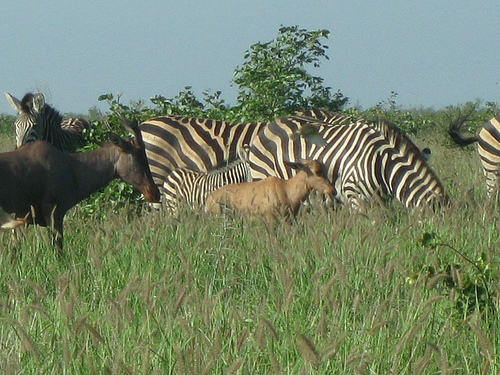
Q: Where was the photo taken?
A: It was taken at the field.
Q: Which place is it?
A: It is a field.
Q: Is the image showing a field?
A: Yes, it is showing a field.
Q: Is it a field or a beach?
A: It is a field.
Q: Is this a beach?
A: No, it is a field.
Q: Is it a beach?
A: No, it is a field.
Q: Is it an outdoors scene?
A: Yes, it is outdoors.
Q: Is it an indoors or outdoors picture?
A: It is outdoors.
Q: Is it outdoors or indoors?
A: It is outdoors.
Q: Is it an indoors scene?
A: No, it is outdoors.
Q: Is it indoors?
A: No, it is outdoors.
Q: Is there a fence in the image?
A: No, there are no fences.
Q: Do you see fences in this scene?
A: No, there are no fences.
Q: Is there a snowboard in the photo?
A: No, there are no snowboards.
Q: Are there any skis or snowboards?
A: No, there are no snowboards or skis.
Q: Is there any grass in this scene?
A: Yes, there is grass.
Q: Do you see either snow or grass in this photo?
A: Yes, there is grass.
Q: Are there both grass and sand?
A: No, there is grass but no sand.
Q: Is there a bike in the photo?
A: No, there are no bikes.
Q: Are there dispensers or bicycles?
A: No, there are no bicycles or dispensers.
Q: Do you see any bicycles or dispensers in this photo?
A: No, there are no bicycles or dispensers.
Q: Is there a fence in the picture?
A: No, there are no fences.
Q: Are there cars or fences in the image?
A: No, there are no fences or cars.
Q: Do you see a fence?
A: No, there are no fences.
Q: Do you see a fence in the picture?
A: No, there are no fences.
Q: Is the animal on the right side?
A: Yes, the animal is on the right of the image.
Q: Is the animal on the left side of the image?
A: No, the animal is on the right of the image.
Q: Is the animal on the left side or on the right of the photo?
A: The animal is on the right of the image.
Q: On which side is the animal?
A: The animal is on the right of the image.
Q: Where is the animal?
A: The animal is in the grass.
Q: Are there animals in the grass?
A: Yes, there is an animal in the grass.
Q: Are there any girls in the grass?
A: No, there is an animal in the grass.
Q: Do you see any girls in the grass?
A: No, there is an animal in the grass.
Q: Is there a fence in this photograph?
A: No, there are no fences.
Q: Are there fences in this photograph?
A: No, there are no fences.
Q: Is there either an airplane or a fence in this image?
A: No, there are no fences or airplanes.